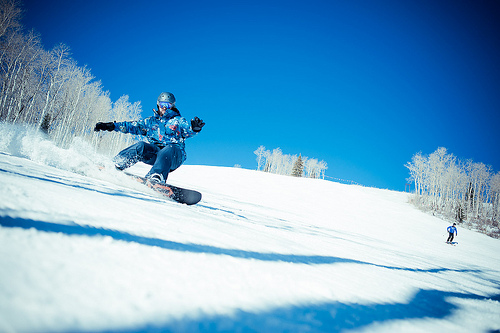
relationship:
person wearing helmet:
[91, 85, 208, 190] [153, 86, 177, 108]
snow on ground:
[1, 121, 499, 331] [2, 148, 499, 330]